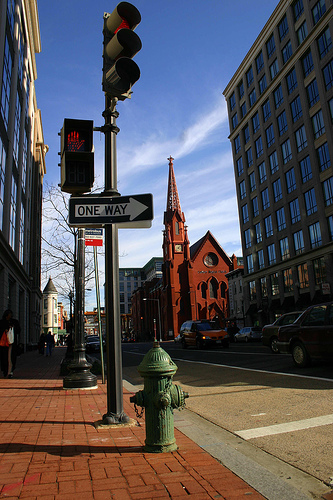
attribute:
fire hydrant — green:
[127, 340, 189, 456]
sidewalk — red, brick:
[4, 345, 270, 500]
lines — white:
[93, 340, 332, 489]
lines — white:
[122, 342, 331, 444]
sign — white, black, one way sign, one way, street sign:
[67, 195, 153, 230]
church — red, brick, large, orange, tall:
[133, 156, 243, 342]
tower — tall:
[164, 156, 190, 340]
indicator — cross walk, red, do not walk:
[57, 119, 96, 194]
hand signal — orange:
[65, 127, 87, 152]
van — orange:
[179, 319, 231, 350]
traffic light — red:
[99, 1, 143, 427]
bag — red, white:
[8, 327, 15, 345]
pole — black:
[103, 95, 135, 432]